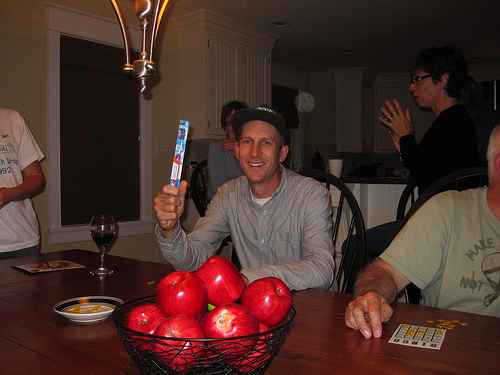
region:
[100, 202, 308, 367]
Basket of apples on the table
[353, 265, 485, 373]
Bingo card on the table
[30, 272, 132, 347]
A bowl on the table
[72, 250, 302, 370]
The apples are red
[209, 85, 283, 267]
He is wearing a hat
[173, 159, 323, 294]
He is wearing a grey shirt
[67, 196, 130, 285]
A wine glass on the table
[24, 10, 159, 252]
A window behind the man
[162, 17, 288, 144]
White cabinets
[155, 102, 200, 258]
He is holding something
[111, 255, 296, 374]
black bowl of red apples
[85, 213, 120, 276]
glass of red wine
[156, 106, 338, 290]
man in black baseball cap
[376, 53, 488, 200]
woman with brown hair and glasses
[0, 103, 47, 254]
man in white t-shirt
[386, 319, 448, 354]
Bingo card with coins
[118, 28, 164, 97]
brass light fixture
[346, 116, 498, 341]
man with white hair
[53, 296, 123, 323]
small bowl of coins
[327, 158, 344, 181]
tall white cup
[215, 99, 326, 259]
Man in black ballcap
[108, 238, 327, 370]
bowl of apples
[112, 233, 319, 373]
Red apples in black basket.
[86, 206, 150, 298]
Wine glass on table.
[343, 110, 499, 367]
Man playing bingo.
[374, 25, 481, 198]
Woman wearing eyeglasses.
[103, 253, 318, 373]
Bowl of red apples.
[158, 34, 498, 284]
Woman standing behind two men.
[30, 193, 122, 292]
Wine glass on wood table.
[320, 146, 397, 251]
styrofoam cup on breakfast bar.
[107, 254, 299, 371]
red apples in black basket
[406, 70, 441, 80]
black glasses on woman's face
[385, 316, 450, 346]
bingo card on brown table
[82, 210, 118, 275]
wine glass on brown table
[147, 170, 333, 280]
grey shirt on man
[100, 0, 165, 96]
silver light fixture above man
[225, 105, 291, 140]
black hat on man's head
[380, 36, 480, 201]
woman is wearing black shirt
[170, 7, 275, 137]
white cabinet is on wall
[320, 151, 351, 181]
white styrofoam cup is on counter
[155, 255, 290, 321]
Three red apples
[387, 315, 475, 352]
A bingo card and bingo chips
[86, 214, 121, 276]
A glass of wine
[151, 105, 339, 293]
A man holding a toothbrush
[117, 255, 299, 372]
apples in a wire basket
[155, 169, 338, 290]
A man's gray shirt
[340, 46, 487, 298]
A woman dressed in black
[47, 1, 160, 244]
a dining room window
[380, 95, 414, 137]
a woman's left hand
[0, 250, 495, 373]
A wooden dining room table